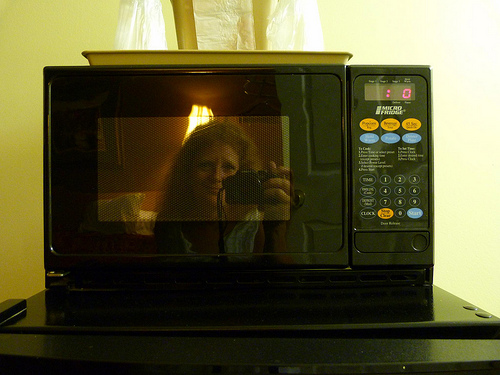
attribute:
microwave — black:
[32, 37, 499, 314]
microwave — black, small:
[36, 55, 438, 288]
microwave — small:
[29, 52, 422, 315]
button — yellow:
[359, 117, 379, 129]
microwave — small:
[34, 32, 439, 324]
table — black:
[65, 305, 267, 347]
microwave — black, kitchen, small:
[40, 62, 437, 322]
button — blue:
[357, 107, 429, 227]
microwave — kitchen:
[12, 47, 459, 321]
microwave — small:
[49, 67, 447, 304]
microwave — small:
[32, 41, 434, 297]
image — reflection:
[102, 119, 289, 221]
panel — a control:
[344, 65, 434, 283]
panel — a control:
[356, 68, 433, 265]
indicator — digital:
[362, 82, 415, 106]